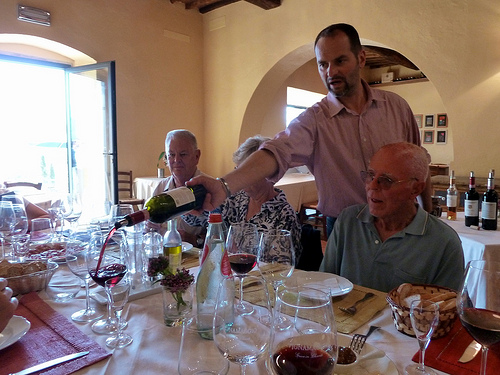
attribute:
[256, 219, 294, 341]
glass — clear, stemmed 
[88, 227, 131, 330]
glass — tall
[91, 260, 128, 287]
wine — red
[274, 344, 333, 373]
wine — red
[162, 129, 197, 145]
hair — grey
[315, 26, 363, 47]
hair — grey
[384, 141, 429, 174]
hair — grey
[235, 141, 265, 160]
hair — grey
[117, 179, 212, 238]
bottle — being poured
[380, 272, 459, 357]
bowl — full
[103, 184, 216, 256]
wine — red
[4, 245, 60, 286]
basket — brown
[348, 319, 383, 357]
fork — gray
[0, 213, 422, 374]
tablecloth — white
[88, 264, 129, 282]
wine — red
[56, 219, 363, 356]
wine glasses — several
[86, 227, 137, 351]
wine glass — tall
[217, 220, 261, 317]
wine glass — tall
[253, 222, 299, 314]
wine glass — tall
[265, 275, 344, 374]
wine glass — tall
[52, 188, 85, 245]
wine glass — tall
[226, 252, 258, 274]
wine — light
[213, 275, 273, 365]
glass — clear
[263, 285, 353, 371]
glass — clear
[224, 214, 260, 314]
glass — clear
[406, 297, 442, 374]
wine glass — clear, stemmed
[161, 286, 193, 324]
glass — clear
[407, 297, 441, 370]
glass — clear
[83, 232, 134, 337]
glass — clear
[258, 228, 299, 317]
glass — clear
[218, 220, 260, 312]
glass — clear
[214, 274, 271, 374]
glass — empty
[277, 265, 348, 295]
plate — white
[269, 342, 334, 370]
wine — red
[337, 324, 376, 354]
fork — silver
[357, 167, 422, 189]
glasses — glass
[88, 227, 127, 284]
wine — red